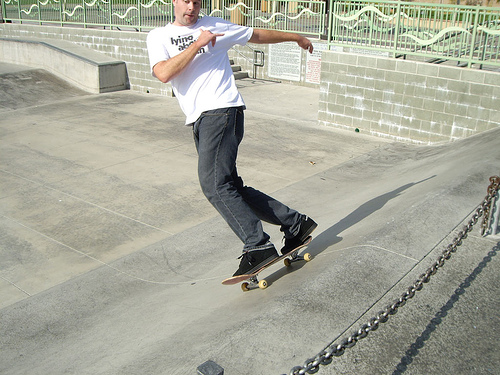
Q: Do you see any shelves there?
A: No, there are no shelves.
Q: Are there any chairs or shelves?
A: No, there are no shelves or chairs.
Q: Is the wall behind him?
A: Yes, the wall is behind the man.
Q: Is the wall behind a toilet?
A: No, the wall is behind the man.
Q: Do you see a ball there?
A: No, there are no balls.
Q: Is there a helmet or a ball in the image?
A: No, there are no balls or helmets.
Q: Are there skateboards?
A: Yes, there is a skateboard.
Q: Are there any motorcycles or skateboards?
A: Yes, there is a skateboard.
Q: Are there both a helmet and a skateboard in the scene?
A: No, there is a skateboard but no helmets.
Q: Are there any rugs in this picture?
A: No, there are no rugs.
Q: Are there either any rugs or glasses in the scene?
A: No, there are no rugs or glasses.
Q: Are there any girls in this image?
A: No, there are no girls.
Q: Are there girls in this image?
A: No, there are no girls.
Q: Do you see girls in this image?
A: No, there are no girls.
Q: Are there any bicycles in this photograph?
A: No, there are no bicycles.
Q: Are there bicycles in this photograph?
A: No, there are no bicycles.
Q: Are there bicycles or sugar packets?
A: No, there are no bicycles or sugar packets.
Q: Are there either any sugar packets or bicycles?
A: No, there are no bicycles or sugar packets.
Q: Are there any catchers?
A: No, there are no catchers.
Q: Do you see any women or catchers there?
A: No, there are no catchers or women.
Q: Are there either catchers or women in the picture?
A: No, there are no catchers or women.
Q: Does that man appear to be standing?
A: Yes, the man is standing.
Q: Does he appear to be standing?
A: Yes, the man is standing.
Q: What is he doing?
A: The man is standing.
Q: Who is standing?
A: The man is standing.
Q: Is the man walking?
A: No, the man is standing.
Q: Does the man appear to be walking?
A: No, the man is standing.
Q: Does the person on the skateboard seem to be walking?
A: No, the man is standing.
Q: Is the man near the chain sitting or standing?
A: The man is standing.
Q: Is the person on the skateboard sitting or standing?
A: The man is standing.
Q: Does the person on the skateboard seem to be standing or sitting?
A: The man is standing.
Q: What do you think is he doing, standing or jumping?
A: The man is standing.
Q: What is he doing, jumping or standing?
A: The man is standing.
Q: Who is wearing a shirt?
A: The man is wearing a shirt.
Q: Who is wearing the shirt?
A: The man is wearing a shirt.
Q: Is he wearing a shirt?
A: Yes, the man is wearing a shirt.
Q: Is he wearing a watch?
A: No, the man is wearing a shirt.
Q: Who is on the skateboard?
A: The man is on the skateboard.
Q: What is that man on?
A: The man is on the skateboard.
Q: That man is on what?
A: The man is on the skateboard.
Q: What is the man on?
A: The man is on the skateboard.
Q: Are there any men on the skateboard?
A: Yes, there is a man on the skateboard.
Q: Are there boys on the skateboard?
A: No, there is a man on the skateboard.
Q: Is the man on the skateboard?
A: Yes, the man is on the skateboard.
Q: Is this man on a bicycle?
A: No, the man is on the skateboard.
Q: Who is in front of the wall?
A: The man is in front of the wall.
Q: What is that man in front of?
A: The man is in front of the wall.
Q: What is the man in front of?
A: The man is in front of the wall.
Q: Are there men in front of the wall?
A: Yes, there is a man in front of the wall.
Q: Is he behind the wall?
A: No, the man is in front of the wall.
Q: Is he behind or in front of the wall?
A: The man is in front of the wall.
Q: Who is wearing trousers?
A: The man is wearing trousers.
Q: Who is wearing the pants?
A: The man is wearing trousers.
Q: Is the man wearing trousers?
A: Yes, the man is wearing trousers.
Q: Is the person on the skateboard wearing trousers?
A: Yes, the man is wearing trousers.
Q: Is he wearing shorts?
A: No, the man is wearing trousers.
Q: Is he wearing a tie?
A: No, the man is wearing a shoe.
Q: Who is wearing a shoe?
A: The man is wearing a shoe.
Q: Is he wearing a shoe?
A: Yes, the man is wearing a shoe.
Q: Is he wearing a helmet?
A: No, the man is wearing a shoe.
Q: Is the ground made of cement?
A: Yes, the ground is made of cement.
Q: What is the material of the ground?
A: The ground is made of cement.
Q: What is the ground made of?
A: The ground is made of concrete.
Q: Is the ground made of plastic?
A: No, the ground is made of concrete.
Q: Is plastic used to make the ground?
A: No, the ground is made of concrete.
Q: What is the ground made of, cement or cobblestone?
A: The ground is made of cement.